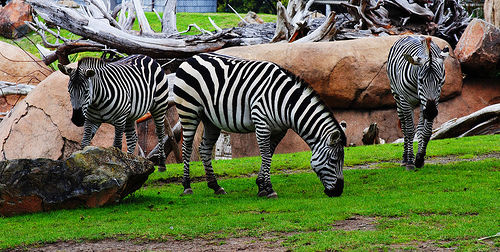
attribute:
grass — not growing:
[362, 170, 449, 212]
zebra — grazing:
[169, 52, 345, 203]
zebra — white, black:
[60, 51, 169, 171]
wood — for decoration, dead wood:
[14, 0, 242, 57]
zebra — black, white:
[152, 52, 370, 207]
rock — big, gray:
[0, 141, 159, 221]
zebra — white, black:
[56, 51, 185, 171]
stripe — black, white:
[176, 52, 214, 92]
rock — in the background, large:
[284, 29, 498, 174]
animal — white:
[172, 43, 375, 209]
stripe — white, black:
[175, 67, 215, 119]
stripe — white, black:
[290, 90, 315, 131]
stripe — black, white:
[221, 70, 284, 125]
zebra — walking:
[356, 42, 460, 147]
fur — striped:
[123, 75, 137, 90]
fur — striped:
[388, 33, 452, 170]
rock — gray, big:
[0, 145, 156, 217]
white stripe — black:
[225, 62, 293, 112]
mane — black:
[304, 76, 318, 96]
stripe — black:
[184, 58, 226, 108]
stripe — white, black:
[176, 57, 216, 107]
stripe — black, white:
[182, 57, 218, 97]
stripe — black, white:
[173, 60, 216, 101]